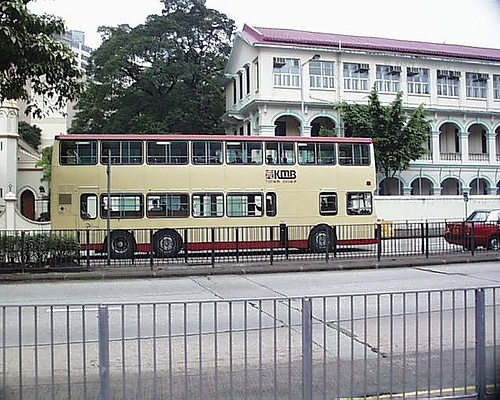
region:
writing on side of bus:
[259, 163, 307, 183]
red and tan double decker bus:
[26, 118, 386, 260]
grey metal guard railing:
[307, 292, 477, 399]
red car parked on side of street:
[438, 200, 498, 250]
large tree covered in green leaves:
[86, 3, 221, 127]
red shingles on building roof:
[249, 17, 498, 62]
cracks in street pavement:
[179, 271, 297, 297]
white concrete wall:
[389, 191, 454, 219]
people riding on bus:
[129, 195, 184, 217]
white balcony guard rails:
[269, 66, 304, 91]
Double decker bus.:
[44, 130, 384, 257]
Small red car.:
[441, 204, 497, 251]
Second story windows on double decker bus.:
[57, 138, 374, 165]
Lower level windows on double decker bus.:
[76, 189, 377, 220]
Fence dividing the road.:
[0, 219, 498, 270]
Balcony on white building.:
[426, 120, 498, 163]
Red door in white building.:
[16, 186, 39, 224]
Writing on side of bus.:
[264, 165, 304, 184]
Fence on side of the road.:
[1, 280, 499, 397]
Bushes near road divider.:
[1, 231, 82, 271]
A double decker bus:
[62, 138, 382, 245]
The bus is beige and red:
[56, 136, 380, 248]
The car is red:
[452, 210, 499, 244]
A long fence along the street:
[106, 223, 487, 259]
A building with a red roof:
[234, 28, 498, 151]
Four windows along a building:
[226, 54, 262, 104]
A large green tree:
[95, 4, 227, 129]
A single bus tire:
[151, 231, 183, 256]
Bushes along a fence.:
[3, 236, 92, 274]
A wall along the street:
[382, 170, 497, 211]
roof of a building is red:
[222, 13, 499, 66]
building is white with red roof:
[234, 19, 496, 141]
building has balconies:
[391, 65, 498, 165]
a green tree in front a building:
[341, 90, 438, 193]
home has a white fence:
[373, 135, 499, 227]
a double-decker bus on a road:
[37, 128, 392, 258]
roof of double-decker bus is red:
[47, 125, 372, 151]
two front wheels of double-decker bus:
[101, 225, 186, 267]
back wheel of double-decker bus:
[302, 215, 345, 255]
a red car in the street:
[435, 201, 497, 257]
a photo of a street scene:
[13, 8, 488, 355]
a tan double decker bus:
[35, 93, 440, 275]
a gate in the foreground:
[5, 285, 497, 381]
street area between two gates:
[5, 205, 499, 347]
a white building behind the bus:
[222, 11, 499, 252]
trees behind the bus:
[3, 0, 270, 195]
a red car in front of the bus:
[443, 189, 498, 256]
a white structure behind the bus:
[2, 50, 98, 276]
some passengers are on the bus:
[78, 181, 295, 231]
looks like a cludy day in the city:
[31, 2, 498, 59]